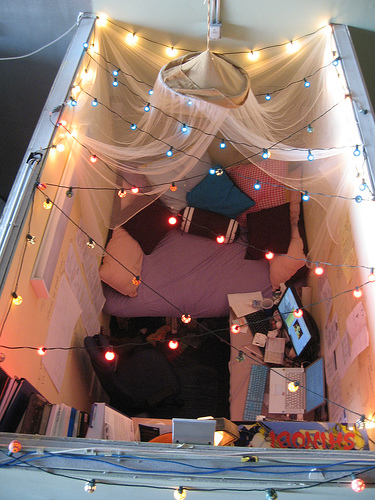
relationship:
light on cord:
[213, 231, 227, 244] [193, 205, 374, 290]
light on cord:
[166, 214, 178, 226] [105, 154, 252, 250]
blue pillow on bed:
[188, 162, 256, 214] [99, 146, 317, 318]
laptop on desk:
[268, 358, 325, 412] [226, 289, 322, 421]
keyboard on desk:
[240, 361, 270, 422] [226, 289, 322, 421]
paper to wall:
[339, 251, 359, 284] [298, 26, 373, 420]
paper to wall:
[344, 302, 372, 365] [298, 26, 373, 420]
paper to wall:
[314, 280, 333, 326] [298, 26, 373, 420]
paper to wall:
[322, 312, 338, 359] [298, 26, 373, 420]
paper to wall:
[333, 332, 350, 380] [298, 26, 373, 420]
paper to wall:
[324, 345, 344, 384] [298, 26, 373, 420]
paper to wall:
[325, 377, 342, 416] [298, 26, 373, 420]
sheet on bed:
[102, 227, 312, 321] [100, 187, 303, 318]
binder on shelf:
[3, 373, 42, 435] [0, 415, 373, 449]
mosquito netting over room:
[70, 97, 322, 184] [17, 221, 337, 477]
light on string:
[300, 193, 310, 201] [98, 22, 357, 68]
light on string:
[129, 122, 139, 131] [85, 162, 177, 205]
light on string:
[90, 98, 99, 108] [74, 82, 374, 205]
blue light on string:
[250, 178, 262, 191] [73, 78, 362, 163]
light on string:
[261, 89, 274, 103] [253, 78, 301, 96]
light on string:
[130, 184, 145, 197] [41, 95, 351, 190]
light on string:
[264, 249, 275, 261] [57, 120, 372, 272]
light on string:
[101, 342, 119, 363] [4, 279, 370, 351]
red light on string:
[215, 231, 226, 244] [57, 120, 372, 272]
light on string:
[166, 214, 178, 226] [1, 10, 374, 431]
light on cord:
[165, 335, 181, 352] [114, 272, 234, 357]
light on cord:
[101, 342, 119, 363] [46, 326, 222, 360]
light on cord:
[260, 88, 273, 103] [59, 200, 104, 249]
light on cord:
[295, 68, 315, 92] [59, 200, 104, 249]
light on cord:
[296, 118, 318, 134] [59, 200, 104, 249]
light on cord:
[257, 140, 273, 165] [59, 200, 104, 249]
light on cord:
[162, 175, 179, 194] [59, 200, 104, 249]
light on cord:
[162, 336, 181, 352] [101, 17, 335, 48]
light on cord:
[101, 342, 119, 363] [204, 163, 351, 207]